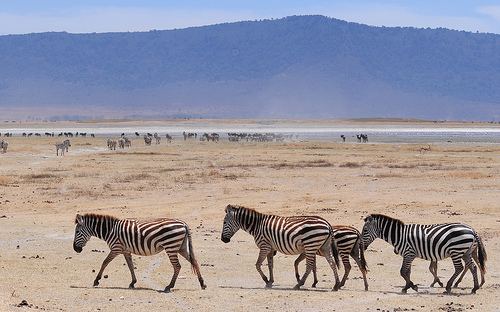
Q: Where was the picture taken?
A: It was taken at the field.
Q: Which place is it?
A: It is a field.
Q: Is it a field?
A: Yes, it is a field.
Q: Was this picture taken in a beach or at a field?
A: It was taken at a field.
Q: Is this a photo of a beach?
A: No, the picture is showing a field.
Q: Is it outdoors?
A: Yes, it is outdoors.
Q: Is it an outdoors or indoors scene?
A: It is outdoors.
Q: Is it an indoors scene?
A: No, it is outdoors.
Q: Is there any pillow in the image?
A: No, there are no pillows.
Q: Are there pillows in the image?
A: No, there are no pillows.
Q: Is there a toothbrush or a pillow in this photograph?
A: No, there are no pillows or toothbrushes.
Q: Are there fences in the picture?
A: No, there are no fences.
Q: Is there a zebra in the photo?
A: Yes, there is a zebra.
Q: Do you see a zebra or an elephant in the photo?
A: Yes, there is a zebra.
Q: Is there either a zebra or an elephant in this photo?
A: Yes, there is a zebra.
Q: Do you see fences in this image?
A: No, there are no fences.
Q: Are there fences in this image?
A: No, there are no fences.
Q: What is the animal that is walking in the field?
A: The animal is a zebra.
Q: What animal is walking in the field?
A: The animal is a zebra.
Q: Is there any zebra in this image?
A: Yes, there is a zebra.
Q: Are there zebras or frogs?
A: Yes, there is a zebra.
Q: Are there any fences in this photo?
A: No, there are no fences.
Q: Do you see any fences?
A: No, there are no fences.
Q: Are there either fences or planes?
A: No, there are no fences or planes.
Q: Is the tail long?
A: Yes, the tail is long.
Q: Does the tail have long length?
A: Yes, the tail is long.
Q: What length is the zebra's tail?
A: The tail is long.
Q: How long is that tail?
A: The tail is long.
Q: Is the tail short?
A: No, the tail is long.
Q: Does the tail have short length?
A: No, the tail is long.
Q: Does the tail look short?
A: No, the tail is long.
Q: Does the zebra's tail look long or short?
A: The tail is long.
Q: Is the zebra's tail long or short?
A: The tail is long.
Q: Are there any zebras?
A: Yes, there is a zebra.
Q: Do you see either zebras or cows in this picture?
A: Yes, there is a zebra.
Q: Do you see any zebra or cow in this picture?
A: Yes, there is a zebra.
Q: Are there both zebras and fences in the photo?
A: No, there is a zebra but no fences.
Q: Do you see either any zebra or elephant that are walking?
A: Yes, the zebra is walking.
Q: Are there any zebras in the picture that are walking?
A: Yes, there is a zebra that is walking.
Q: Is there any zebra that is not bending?
A: Yes, there is a zebra that is walking.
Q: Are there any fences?
A: No, there are no fences.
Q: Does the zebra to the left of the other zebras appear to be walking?
A: Yes, the zebra is walking.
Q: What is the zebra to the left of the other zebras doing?
A: The zebra is walking.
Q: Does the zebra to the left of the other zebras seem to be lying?
A: No, the zebra is walking.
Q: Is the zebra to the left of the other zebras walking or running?
A: The zebra is walking.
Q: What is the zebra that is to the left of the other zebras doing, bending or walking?
A: The zebra is walking.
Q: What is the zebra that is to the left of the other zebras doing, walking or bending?
A: The zebra is walking.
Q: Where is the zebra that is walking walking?
A: The zebra is walking in the field.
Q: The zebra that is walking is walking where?
A: The zebra is walking in the field.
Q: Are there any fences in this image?
A: No, there are no fences.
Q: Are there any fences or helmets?
A: No, there are no fences or helmets.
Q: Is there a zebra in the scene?
A: Yes, there are zebras.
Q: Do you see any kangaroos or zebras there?
A: Yes, there are zebras.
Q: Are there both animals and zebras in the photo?
A: Yes, there are both zebras and animals.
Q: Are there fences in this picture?
A: No, there are no fences.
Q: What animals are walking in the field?
A: The animals are zebras.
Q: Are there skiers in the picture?
A: No, there are no skiers.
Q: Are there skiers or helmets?
A: No, there are no skiers or helmets.